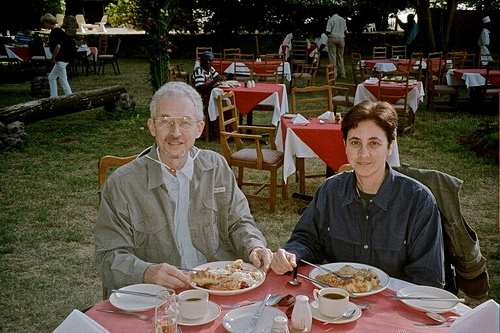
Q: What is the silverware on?
A: The silverware is on the plate.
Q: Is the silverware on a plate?
A: Yes, the silverware is on a plate.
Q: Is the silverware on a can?
A: No, the silverware is on a plate.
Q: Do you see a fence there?
A: No, there are no fences.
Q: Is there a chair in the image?
A: Yes, there is a chair.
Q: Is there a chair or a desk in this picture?
A: Yes, there is a chair.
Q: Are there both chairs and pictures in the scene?
A: No, there is a chair but no pictures.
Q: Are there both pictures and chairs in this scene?
A: No, there is a chair but no pictures.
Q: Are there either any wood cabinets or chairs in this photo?
A: Yes, there is a wood chair.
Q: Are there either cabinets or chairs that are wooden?
A: Yes, the chair is wooden.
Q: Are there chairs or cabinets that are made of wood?
A: Yes, the chair is made of wood.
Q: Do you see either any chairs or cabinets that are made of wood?
A: Yes, the chair is made of wood.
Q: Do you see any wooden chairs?
A: Yes, there is a wood chair.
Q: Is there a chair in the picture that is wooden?
A: Yes, there is a chair that is wooden.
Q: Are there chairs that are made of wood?
A: Yes, there is a chair that is made of wood.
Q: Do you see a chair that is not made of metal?
A: Yes, there is a chair that is made of wood.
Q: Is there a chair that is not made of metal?
A: Yes, there is a chair that is made of wood.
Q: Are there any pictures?
A: No, there are no pictures.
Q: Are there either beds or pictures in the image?
A: No, there are no pictures or beds.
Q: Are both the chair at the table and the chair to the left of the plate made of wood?
A: Yes, both the chair and the chair are made of wood.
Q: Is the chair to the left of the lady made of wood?
A: Yes, the chair is made of wood.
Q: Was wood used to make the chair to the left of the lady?
A: Yes, the chair is made of wood.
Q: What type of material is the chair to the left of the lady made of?
A: The chair is made of wood.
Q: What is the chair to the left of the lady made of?
A: The chair is made of wood.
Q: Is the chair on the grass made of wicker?
A: No, the chair is made of wood.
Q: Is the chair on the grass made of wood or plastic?
A: The chair is made of wood.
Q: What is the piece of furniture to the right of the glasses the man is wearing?
A: The piece of furniture is a chair.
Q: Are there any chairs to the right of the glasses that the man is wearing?
A: Yes, there is a chair to the right of the glasses.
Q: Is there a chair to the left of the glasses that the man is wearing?
A: No, the chair is to the right of the glasses.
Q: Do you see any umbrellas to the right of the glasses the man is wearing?
A: No, there is a chair to the right of the glasses.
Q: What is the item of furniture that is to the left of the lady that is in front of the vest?
A: The piece of furniture is a chair.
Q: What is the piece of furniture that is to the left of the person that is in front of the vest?
A: The piece of furniture is a chair.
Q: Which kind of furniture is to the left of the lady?
A: The piece of furniture is a chair.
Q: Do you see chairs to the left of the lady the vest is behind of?
A: Yes, there is a chair to the left of the lady.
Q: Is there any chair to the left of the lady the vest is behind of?
A: Yes, there is a chair to the left of the lady.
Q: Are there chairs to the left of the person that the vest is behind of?
A: Yes, there is a chair to the left of the lady.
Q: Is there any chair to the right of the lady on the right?
A: No, the chair is to the left of the lady.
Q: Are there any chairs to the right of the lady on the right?
A: No, the chair is to the left of the lady.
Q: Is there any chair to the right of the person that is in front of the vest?
A: No, the chair is to the left of the lady.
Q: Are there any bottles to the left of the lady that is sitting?
A: No, there is a chair to the left of the lady.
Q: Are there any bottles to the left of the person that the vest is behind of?
A: No, there is a chair to the left of the lady.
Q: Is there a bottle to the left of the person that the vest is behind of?
A: No, there is a chair to the left of the lady.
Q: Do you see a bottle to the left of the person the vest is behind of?
A: No, there is a chair to the left of the lady.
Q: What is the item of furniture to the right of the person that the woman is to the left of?
A: The piece of furniture is a chair.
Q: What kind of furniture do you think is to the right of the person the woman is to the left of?
A: The piece of furniture is a chair.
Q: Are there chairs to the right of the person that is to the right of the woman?
A: Yes, there is a chair to the right of the person.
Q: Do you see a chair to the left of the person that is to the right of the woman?
A: No, the chair is to the right of the person.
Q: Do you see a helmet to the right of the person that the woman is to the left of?
A: No, there is a chair to the right of the person.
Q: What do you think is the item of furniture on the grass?
A: The piece of furniture is a chair.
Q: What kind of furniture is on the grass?
A: The piece of furniture is a chair.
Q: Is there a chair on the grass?
A: Yes, there is a chair on the grass.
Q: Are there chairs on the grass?
A: Yes, there is a chair on the grass.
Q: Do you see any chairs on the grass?
A: Yes, there is a chair on the grass.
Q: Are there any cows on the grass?
A: No, there is a chair on the grass.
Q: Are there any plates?
A: Yes, there is a plate.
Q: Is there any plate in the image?
A: Yes, there is a plate.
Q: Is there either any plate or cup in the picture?
A: Yes, there is a plate.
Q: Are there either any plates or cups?
A: Yes, there is a plate.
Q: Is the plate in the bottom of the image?
A: Yes, the plate is in the bottom of the image.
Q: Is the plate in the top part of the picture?
A: No, the plate is in the bottom of the image.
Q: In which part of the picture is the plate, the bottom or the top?
A: The plate is in the bottom of the image.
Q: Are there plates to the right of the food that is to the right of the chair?
A: Yes, there is a plate to the right of the food.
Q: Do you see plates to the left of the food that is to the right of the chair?
A: No, the plate is to the right of the food.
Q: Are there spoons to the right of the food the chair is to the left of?
A: No, there is a plate to the right of the food.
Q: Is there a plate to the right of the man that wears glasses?
A: Yes, there is a plate to the right of the man.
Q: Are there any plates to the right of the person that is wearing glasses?
A: Yes, there is a plate to the right of the man.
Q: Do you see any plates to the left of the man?
A: No, the plate is to the right of the man.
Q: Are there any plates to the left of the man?
A: No, the plate is to the right of the man.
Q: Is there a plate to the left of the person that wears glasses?
A: No, the plate is to the right of the man.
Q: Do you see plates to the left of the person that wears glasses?
A: No, the plate is to the right of the man.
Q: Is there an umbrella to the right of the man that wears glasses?
A: No, there is a plate to the right of the man.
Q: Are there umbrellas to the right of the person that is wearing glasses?
A: No, there is a plate to the right of the man.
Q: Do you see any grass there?
A: Yes, there is grass.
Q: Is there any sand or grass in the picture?
A: Yes, there is grass.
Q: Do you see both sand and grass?
A: No, there is grass but no sand.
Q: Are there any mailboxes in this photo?
A: No, there are no mailboxes.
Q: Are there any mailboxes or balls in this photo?
A: No, there are no mailboxes or balls.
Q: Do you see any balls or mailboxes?
A: No, there are no mailboxes or balls.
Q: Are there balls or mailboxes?
A: No, there are no mailboxes or balls.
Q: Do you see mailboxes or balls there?
A: No, there are no mailboxes or balls.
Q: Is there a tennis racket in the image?
A: No, there are no rackets.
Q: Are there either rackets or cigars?
A: No, there are no rackets or cigars.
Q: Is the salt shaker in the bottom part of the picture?
A: Yes, the salt shaker is in the bottom of the image.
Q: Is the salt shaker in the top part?
A: No, the salt shaker is in the bottom of the image.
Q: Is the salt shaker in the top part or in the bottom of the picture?
A: The salt shaker is in the bottom of the image.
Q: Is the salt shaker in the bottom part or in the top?
A: The salt shaker is in the bottom of the image.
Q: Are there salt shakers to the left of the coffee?
A: Yes, there is a salt shaker to the left of the coffee.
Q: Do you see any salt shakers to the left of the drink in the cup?
A: Yes, there is a salt shaker to the left of the coffee.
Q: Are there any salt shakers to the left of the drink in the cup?
A: Yes, there is a salt shaker to the left of the coffee.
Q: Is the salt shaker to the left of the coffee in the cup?
A: Yes, the salt shaker is to the left of the coffee.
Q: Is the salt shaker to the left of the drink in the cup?
A: Yes, the salt shaker is to the left of the coffee.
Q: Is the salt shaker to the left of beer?
A: No, the salt shaker is to the left of the coffee.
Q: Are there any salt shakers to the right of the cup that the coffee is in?
A: No, the salt shaker is to the left of the cup.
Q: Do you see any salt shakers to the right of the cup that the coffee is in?
A: No, the salt shaker is to the left of the cup.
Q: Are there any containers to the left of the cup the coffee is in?
A: No, there is a salt shaker to the left of the cup.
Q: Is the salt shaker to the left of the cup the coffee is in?
A: Yes, the salt shaker is to the left of the cup.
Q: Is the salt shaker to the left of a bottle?
A: No, the salt shaker is to the left of the cup.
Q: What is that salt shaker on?
A: The salt shaker is on the table.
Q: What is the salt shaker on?
A: The salt shaker is on the table.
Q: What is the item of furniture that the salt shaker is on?
A: The piece of furniture is a table.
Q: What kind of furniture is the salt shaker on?
A: The salt shaker is on the table.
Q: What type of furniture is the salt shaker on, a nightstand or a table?
A: The salt shaker is on a table.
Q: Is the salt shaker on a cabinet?
A: No, the salt shaker is on the table.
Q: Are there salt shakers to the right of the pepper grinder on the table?
A: Yes, there is a salt shaker to the right of the pepper grinder.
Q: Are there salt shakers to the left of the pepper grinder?
A: No, the salt shaker is to the right of the pepper grinder.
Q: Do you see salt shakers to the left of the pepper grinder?
A: No, the salt shaker is to the right of the pepper grinder.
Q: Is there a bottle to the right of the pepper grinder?
A: No, there is a salt shaker to the right of the pepper grinder.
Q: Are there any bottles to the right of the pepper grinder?
A: No, there is a salt shaker to the right of the pepper grinder.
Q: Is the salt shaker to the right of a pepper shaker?
A: Yes, the salt shaker is to the right of a pepper shaker.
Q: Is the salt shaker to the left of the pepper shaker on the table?
A: No, the salt shaker is to the right of the pepper shaker.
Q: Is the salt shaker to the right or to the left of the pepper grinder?
A: The salt shaker is to the right of the pepper grinder.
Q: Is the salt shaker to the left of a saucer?
A: Yes, the salt shaker is to the left of a saucer.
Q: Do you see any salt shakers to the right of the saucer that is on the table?
A: Yes, there is a salt shaker to the right of the saucer.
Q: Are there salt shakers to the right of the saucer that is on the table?
A: Yes, there is a salt shaker to the right of the saucer.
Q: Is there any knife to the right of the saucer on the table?
A: No, there is a salt shaker to the right of the saucer.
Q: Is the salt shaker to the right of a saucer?
A: Yes, the salt shaker is to the right of a saucer.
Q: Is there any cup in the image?
A: Yes, there is a cup.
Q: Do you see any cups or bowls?
A: Yes, there is a cup.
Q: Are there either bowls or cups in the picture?
A: Yes, there is a cup.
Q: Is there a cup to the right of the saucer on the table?
A: Yes, there is a cup to the right of the saucer.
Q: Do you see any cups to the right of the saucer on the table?
A: Yes, there is a cup to the right of the saucer.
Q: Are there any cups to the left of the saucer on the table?
A: No, the cup is to the right of the saucer.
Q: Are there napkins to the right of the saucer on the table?
A: No, there is a cup to the right of the saucer.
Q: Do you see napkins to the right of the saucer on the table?
A: No, there is a cup to the right of the saucer.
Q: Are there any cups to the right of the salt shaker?
A: Yes, there is a cup to the right of the salt shaker.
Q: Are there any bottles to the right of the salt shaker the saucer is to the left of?
A: No, there is a cup to the right of the salt shaker.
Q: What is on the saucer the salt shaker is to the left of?
A: The cup is on the saucer.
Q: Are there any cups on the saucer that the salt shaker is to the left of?
A: Yes, there is a cup on the saucer.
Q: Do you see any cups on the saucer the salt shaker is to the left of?
A: Yes, there is a cup on the saucer.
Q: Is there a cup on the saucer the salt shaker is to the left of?
A: Yes, there is a cup on the saucer.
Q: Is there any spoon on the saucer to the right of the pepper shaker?
A: No, there is a cup on the saucer.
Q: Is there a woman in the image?
A: Yes, there is a woman.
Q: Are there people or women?
A: Yes, there is a woman.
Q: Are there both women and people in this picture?
A: Yes, there are both a woman and a person.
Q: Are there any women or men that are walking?
A: Yes, the woman is walking.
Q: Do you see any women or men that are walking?
A: Yes, the woman is walking.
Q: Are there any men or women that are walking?
A: Yes, the woman is walking.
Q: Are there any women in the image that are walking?
A: Yes, there is a woman that is walking.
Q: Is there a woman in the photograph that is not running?
A: Yes, there is a woman that is walking.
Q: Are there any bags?
A: No, there are no bags.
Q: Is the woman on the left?
A: Yes, the woman is on the left of the image.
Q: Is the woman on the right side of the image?
A: No, the woman is on the left of the image.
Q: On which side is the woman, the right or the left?
A: The woman is on the left of the image.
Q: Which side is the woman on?
A: The woman is on the left of the image.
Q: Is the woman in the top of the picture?
A: Yes, the woman is in the top of the image.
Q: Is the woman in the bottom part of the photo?
A: No, the woman is in the top of the image.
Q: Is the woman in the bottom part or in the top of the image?
A: The woman is in the top of the image.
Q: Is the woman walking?
A: Yes, the woman is walking.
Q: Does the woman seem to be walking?
A: Yes, the woman is walking.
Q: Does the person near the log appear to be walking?
A: Yes, the woman is walking.